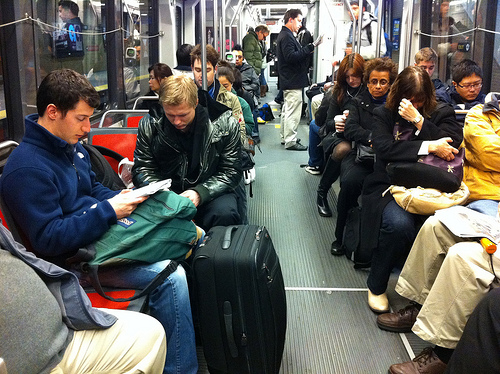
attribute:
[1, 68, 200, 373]
man — reading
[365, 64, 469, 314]
person — sleeping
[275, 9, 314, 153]
man — standing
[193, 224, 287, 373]
suitcase — black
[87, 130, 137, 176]
seat — orange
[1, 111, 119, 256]
coat — blue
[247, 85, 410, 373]
aisle — clean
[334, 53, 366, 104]
hair — red brown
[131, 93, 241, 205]
jacket — army colored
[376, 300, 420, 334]
shoe — brown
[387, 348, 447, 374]
shoe — brown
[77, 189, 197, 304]
backpack — green